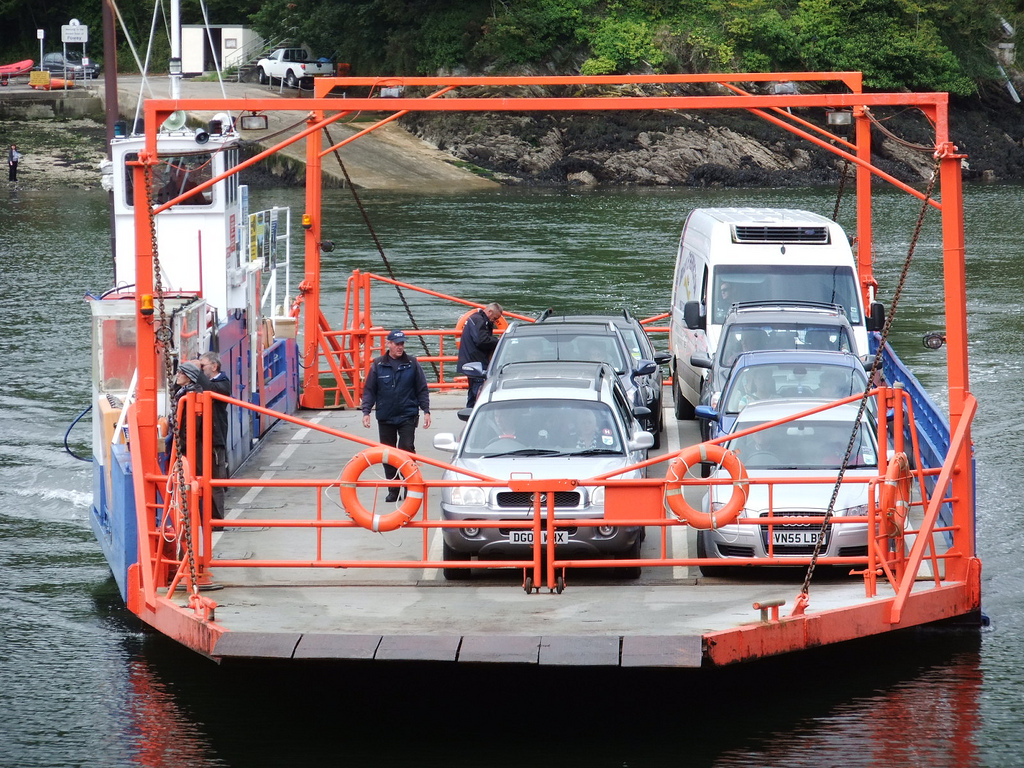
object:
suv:
[706, 286, 862, 404]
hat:
[381, 326, 410, 345]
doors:
[217, 308, 258, 471]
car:
[39, 45, 97, 78]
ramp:
[75, 67, 504, 194]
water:
[0, 662, 482, 766]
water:
[0, 188, 77, 767]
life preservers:
[325, 448, 450, 532]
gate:
[198, 392, 912, 652]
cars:
[479, 316, 645, 360]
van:
[664, 193, 887, 426]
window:
[147, 173, 215, 206]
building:
[80, 119, 298, 479]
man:
[351, 315, 436, 493]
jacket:
[359, 351, 431, 420]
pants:
[370, 419, 425, 489]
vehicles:
[461, 302, 672, 436]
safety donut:
[651, 438, 757, 534]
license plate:
[758, 509, 832, 546]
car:
[687, 389, 914, 578]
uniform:
[362, 360, 430, 492]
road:
[198, 78, 472, 188]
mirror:
[673, 289, 712, 337]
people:
[477, 408, 612, 452]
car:
[430, 378, 660, 589]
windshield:
[720, 362, 868, 404]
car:
[703, 342, 886, 457]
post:
[841, 69, 893, 336]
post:
[929, 87, 976, 582]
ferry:
[87, 69, 984, 678]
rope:
[860, 102, 947, 154]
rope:
[802, 152, 945, 595]